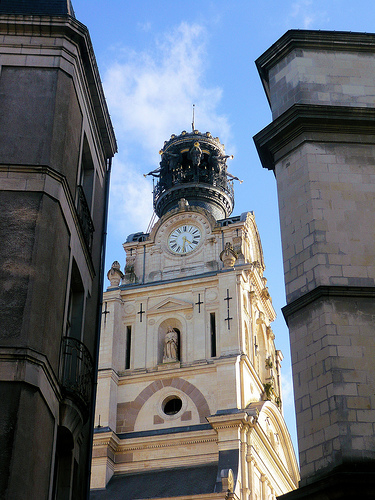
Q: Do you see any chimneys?
A: No, there are no chimneys.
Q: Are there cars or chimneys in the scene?
A: No, there are no chimneys or cars.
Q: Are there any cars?
A: No, there are no cars.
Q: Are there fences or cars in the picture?
A: No, there are no cars or fences.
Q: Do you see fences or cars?
A: No, there are no cars or fences.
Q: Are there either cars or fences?
A: No, there are no cars or fences.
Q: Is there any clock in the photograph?
A: Yes, there is a clock.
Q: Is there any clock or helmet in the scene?
A: Yes, there is a clock.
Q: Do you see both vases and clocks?
A: No, there is a clock but no vases.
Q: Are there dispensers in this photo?
A: No, there are no dispensers.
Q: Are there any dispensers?
A: No, there are no dispensers.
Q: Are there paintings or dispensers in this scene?
A: No, there are no dispensers or paintings.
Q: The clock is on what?
A: The clock is on the building.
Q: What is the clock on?
A: The clock is on the building.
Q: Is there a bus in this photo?
A: No, there are no buses.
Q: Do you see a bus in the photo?
A: No, there are no buses.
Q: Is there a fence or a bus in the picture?
A: No, there are no buses or fences.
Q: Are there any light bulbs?
A: No, there are no light bulbs.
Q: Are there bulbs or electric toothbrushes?
A: No, there are no bulbs or electric toothbrushes.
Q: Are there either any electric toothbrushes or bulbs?
A: No, there are no bulbs or electric toothbrushes.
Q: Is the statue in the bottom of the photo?
A: Yes, the statue is in the bottom of the image.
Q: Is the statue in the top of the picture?
A: No, the statue is in the bottom of the image.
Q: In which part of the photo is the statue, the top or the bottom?
A: The statue is in the bottom of the image.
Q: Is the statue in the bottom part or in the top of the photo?
A: The statue is in the bottom of the image.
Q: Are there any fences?
A: No, there are no fences.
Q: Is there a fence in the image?
A: No, there are no fences.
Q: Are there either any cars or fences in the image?
A: No, there are no fences or cars.